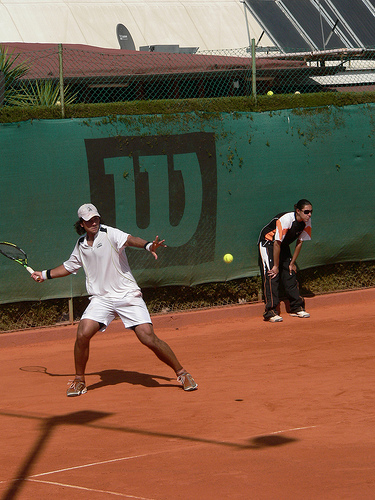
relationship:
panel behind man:
[225, 3, 375, 56] [3, 191, 212, 410]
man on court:
[3, 191, 212, 410] [6, 310, 372, 499]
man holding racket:
[3, 191, 212, 410] [1, 236, 45, 285]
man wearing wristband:
[3, 191, 212, 410] [39, 264, 55, 284]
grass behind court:
[6, 97, 370, 110] [6, 310, 372, 499]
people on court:
[6, 162, 353, 406] [6, 310, 372, 499]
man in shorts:
[3, 191, 212, 410] [70, 292, 163, 336]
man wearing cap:
[3, 191, 212, 410] [71, 201, 102, 223]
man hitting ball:
[3, 191, 212, 410] [215, 250, 238, 265]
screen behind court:
[0, 94, 374, 312] [6, 310, 372, 499]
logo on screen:
[70, 129, 236, 269] [0, 94, 374, 312]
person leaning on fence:
[243, 180, 340, 329] [0, 39, 372, 301]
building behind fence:
[2, 39, 327, 103] [0, 39, 372, 301]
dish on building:
[111, 19, 159, 60] [2, 39, 327, 103]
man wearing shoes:
[3, 191, 212, 410] [56, 369, 202, 399]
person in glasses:
[243, 180, 340, 329] [298, 205, 314, 217]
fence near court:
[0, 39, 372, 301] [6, 310, 372, 499]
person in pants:
[243, 180, 340, 329] [249, 241, 310, 315]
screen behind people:
[0, 94, 374, 312] [6, 162, 353, 406]